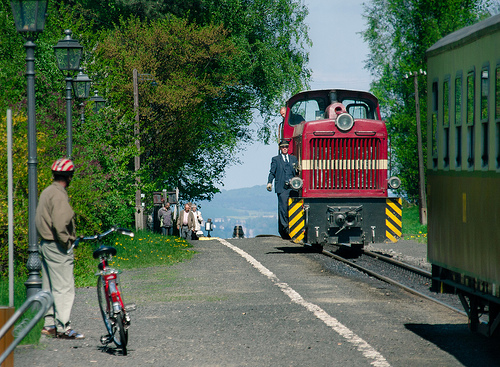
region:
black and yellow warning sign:
[286, 199, 311, 250]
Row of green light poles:
[11, 16, 137, 314]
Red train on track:
[256, 76, 426, 278]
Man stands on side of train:
[261, 126, 318, 253]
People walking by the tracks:
[149, 190, 229, 260]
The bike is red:
[82, 228, 168, 349]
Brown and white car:
[404, 8, 490, 324]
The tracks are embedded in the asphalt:
[274, 213, 469, 346]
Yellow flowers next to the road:
[66, 229, 216, 262]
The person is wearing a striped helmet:
[36, 148, 120, 327]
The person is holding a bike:
[36, 153, 129, 353]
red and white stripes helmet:
[48, 155, 76, 172]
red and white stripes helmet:
[39, 156, 79, 180]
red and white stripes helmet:
[54, 156, 71, 179]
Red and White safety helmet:
[51, 157, 78, 175]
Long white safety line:
[263, 268, 314, 312]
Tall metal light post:
[54, 29, 84, 154]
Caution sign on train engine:
[286, 193, 306, 242]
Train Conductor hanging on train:
[267, 138, 294, 233]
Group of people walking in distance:
[161, 201, 206, 237]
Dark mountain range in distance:
[218, 180, 265, 214]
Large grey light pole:
[402, 63, 429, 223]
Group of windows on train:
[428, 75, 497, 180]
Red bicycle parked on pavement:
[91, 241, 141, 347]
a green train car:
[416, 10, 497, 337]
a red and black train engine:
[285, 80, 396, 240]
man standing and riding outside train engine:
[260, 125, 310, 242]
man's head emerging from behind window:
[275, 95, 325, 127]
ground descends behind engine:
[200, 86, 385, 266]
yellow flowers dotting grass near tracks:
[115, 232, 390, 317]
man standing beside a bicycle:
[28, 156, 143, 355]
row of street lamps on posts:
[10, 3, 110, 333]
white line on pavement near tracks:
[198, 230, 425, 361]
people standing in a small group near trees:
[110, 5, 257, 246]